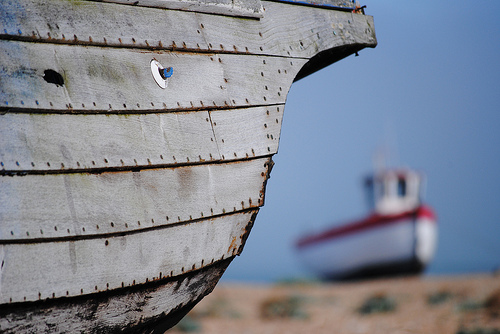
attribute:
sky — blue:
[402, 70, 460, 140]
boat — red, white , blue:
[296, 153, 452, 289]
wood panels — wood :
[17, 35, 268, 330]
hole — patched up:
[144, 52, 179, 90]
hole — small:
[25, 54, 85, 111]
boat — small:
[284, 160, 446, 282]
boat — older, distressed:
[0, 2, 380, 322]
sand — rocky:
[242, 290, 349, 330]